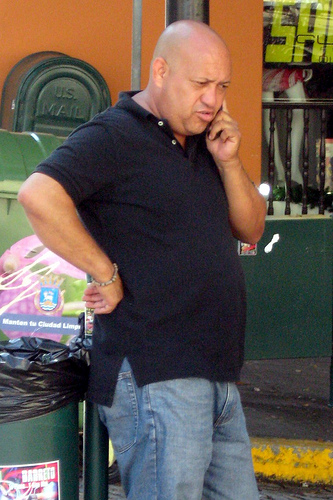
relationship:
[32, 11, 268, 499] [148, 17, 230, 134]
man with head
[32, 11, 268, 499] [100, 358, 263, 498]
man with blue jeans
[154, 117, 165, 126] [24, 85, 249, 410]
button on a shirt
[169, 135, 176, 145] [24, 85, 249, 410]
button on a shirt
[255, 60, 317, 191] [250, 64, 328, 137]
mannequin in window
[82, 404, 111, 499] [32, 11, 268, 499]
green pole behind man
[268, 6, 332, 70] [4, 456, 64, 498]
lettering on a sign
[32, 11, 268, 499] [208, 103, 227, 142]
man on phone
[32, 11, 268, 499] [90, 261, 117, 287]
man wearing a bracelet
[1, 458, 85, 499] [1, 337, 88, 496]
sticker on garbage can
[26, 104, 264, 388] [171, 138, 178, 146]
shirt has button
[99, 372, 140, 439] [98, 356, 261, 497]
pocket on jeans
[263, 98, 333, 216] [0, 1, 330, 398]
fence on building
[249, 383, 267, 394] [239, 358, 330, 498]
pebbles on ground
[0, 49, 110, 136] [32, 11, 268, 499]
mailbox behind man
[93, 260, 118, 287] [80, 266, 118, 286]
bracelet on wrist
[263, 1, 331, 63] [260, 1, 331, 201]
sign in window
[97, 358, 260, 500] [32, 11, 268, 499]
blue jeans of man